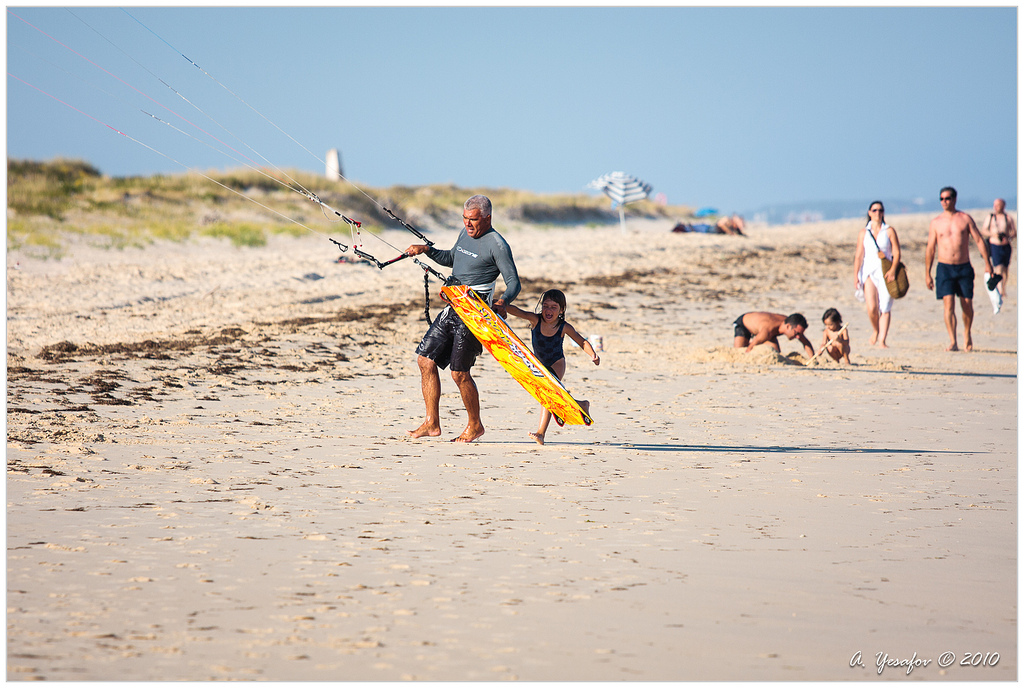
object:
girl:
[492, 288, 601, 446]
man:
[400, 195, 521, 442]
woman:
[854, 200, 900, 350]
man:
[731, 311, 819, 367]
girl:
[818, 307, 850, 368]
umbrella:
[584, 170, 653, 205]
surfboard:
[438, 285, 592, 427]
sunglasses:
[941, 197, 954, 200]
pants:
[936, 262, 975, 301]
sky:
[5, 0, 1024, 215]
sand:
[0, 209, 1019, 688]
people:
[923, 186, 992, 354]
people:
[980, 198, 1016, 306]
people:
[854, 202, 901, 348]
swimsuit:
[529, 313, 568, 374]